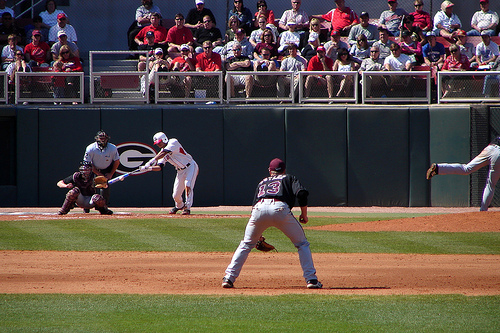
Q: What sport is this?
A: Baseball.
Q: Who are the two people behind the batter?
A: Catcher and umpire.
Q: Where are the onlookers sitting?
A: Bleachers.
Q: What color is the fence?
A: White.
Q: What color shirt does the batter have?
A: White and red.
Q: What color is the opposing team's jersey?
A: Black.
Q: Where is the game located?
A: Baseball stadium.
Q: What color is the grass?
A: Green.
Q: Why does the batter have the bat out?
A: He's about to hit the ball.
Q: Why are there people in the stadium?
A: To watch the baseball game.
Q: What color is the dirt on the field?
A: Brown.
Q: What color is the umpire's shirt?
A: Light blue.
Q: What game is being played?
A: Baseball.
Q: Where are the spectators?
A: In the stands.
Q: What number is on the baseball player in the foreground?
A: 13.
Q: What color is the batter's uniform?
A: White.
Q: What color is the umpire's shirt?
A: Light blue.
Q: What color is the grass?
A: Green.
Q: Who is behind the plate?
A: Catcher and Umpire.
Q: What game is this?
A: Baseball.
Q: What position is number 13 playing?
A: Pitcher.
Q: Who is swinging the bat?
A: The batter.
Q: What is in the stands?
A: Spectators.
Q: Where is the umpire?
A: Behind the catcher.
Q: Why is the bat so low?
A: In order to make contact with the ball.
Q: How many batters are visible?
A: One.